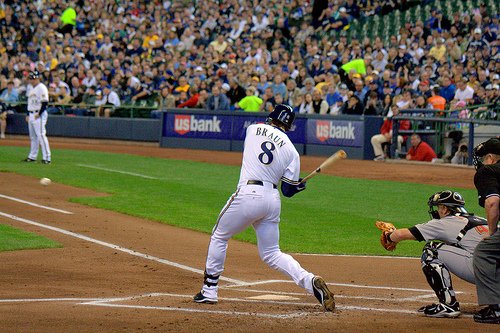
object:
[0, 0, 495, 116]
stands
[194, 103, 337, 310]
player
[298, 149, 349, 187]
bat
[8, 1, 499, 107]
crowd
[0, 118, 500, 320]
game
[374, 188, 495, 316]
catcher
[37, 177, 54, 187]
ball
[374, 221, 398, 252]
glove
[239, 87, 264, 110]
person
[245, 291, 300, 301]
base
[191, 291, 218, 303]
shoe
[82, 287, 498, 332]
ground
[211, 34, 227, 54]
person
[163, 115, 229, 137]
ad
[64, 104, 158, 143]
backboard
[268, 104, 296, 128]
helmet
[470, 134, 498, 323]
umpire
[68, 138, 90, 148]
air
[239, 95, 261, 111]
shirt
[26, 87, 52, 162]
uniform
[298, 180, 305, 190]
hand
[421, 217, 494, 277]
gray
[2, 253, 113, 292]
dirt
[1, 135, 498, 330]
field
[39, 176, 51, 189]
baseball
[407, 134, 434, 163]
man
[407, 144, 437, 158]
jacket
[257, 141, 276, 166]
number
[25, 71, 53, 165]
player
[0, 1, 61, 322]
side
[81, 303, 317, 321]
lines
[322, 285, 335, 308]
cleats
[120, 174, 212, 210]
grass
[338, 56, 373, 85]
vendor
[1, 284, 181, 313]
chalk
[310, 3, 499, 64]
area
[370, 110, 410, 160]
men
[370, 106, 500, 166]
dugout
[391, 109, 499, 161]
raling